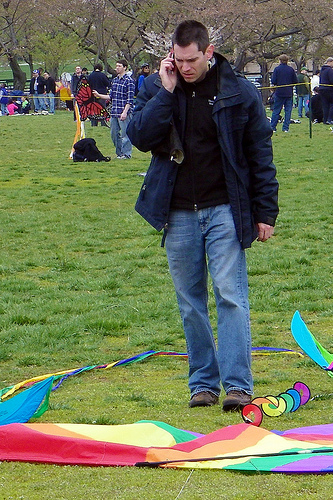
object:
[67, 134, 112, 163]
bag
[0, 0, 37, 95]
tree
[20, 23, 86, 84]
trees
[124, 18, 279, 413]
person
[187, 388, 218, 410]
foot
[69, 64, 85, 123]
person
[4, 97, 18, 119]
kids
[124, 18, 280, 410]
guy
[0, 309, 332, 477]
kite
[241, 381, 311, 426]
tail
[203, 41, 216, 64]
ear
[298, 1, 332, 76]
trees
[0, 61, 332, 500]
park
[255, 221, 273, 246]
hand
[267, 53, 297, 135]
people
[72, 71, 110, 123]
butterfly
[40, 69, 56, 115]
people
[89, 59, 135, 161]
people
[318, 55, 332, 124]
people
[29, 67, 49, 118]
people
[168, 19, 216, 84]
head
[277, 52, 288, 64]
head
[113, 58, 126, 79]
head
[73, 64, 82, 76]
head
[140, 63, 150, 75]
head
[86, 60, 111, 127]
person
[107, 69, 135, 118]
plaid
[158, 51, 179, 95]
hand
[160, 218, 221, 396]
leg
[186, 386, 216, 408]
feet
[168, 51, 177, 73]
cellphone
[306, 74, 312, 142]
post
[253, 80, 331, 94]
rope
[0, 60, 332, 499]
field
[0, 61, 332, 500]
ground